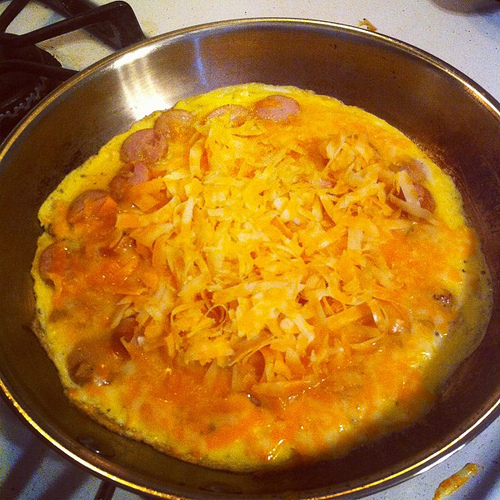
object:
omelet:
[32, 82, 495, 474]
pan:
[0, 17, 499, 500]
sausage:
[257, 94, 301, 118]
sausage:
[162, 114, 198, 141]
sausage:
[68, 189, 109, 217]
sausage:
[120, 129, 156, 158]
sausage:
[38, 238, 73, 282]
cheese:
[120, 119, 434, 392]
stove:
[0, 0, 497, 499]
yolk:
[398, 372, 429, 412]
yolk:
[165, 380, 199, 409]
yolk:
[409, 264, 441, 286]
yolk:
[202, 419, 250, 452]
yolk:
[274, 426, 296, 442]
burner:
[0, 0, 145, 142]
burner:
[93, 478, 111, 498]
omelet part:
[435, 463, 476, 499]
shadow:
[0, 400, 90, 500]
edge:
[12, 0, 146, 51]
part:
[116, 4, 126, 18]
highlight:
[105, 46, 173, 121]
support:
[3, 0, 147, 135]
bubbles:
[58, 170, 103, 188]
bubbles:
[460, 261, 495, 307]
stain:
[362, 18, 376, 31]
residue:
[149, 489, 183, 499]